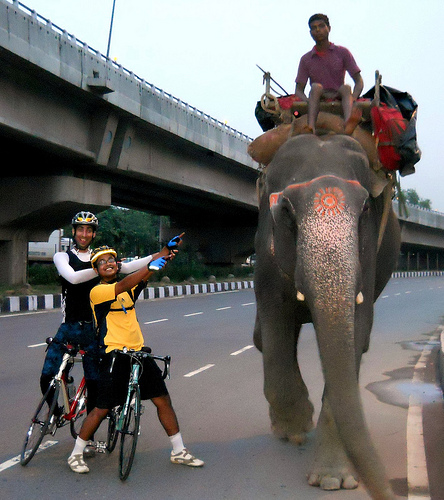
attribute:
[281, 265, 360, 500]
tusk — large and gray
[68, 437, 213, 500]
sneakers — gray and white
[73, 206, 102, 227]
helmet — multi colored bike 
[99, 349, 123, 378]
bottle — dark green water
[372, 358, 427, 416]
spot — large water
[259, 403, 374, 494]
toes — elephant 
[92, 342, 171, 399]
shorts — pair , black 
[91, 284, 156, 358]
shirt — person's bright yellow 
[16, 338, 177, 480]
bicycle — light blue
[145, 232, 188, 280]
gloves — blue cycling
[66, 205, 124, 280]
faces — people's, smiling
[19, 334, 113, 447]
bicycle — red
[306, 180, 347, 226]
marking — orange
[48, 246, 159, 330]
shirt — black, white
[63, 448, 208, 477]
shoes — white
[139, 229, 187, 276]
gloves — blue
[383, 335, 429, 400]
puddles — water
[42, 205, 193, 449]
boy — tall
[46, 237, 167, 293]
white shirt — long sleeve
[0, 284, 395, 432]
curb — black, white, striped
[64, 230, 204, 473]
boy — young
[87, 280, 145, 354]
shirt — yellow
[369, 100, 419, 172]
back pack — red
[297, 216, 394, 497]
elephant trunk — really long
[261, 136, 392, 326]
head — elephant's, painted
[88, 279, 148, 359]
shirt — yellow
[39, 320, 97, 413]
pants — blue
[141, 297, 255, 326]
dividers — white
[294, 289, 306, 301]
tusk — elephant's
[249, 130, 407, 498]
elephant — grey, tall